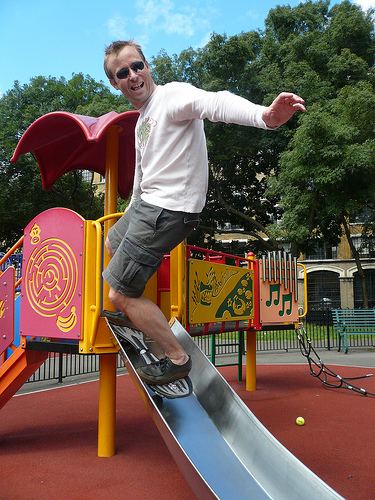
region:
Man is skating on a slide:
[82, 33, 324, 395]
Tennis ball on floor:
[292, 410, 307, 432]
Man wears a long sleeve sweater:
[81, 25, 319, 407]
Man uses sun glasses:
[85, 27, 322, 398]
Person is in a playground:
[15, 38, 367, 498]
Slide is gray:
[91, 305, 358, 498]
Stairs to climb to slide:
[1, 237, 50, 433]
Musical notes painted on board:
[259, 280, 296, 319]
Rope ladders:
[288, 323, 372, 394]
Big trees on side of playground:
[211, 2, 370, 246]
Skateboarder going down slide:
[97, 37, 305, 382]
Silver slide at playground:
[97, 302, 339, 494]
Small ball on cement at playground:
[293, 409, 302, 424]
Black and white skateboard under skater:
[110, 317, 189, 397]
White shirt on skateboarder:
[126, 87, 267, 212]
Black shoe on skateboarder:
[135, 352, 191, 385]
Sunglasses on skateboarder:
[111, 58, 146, 79]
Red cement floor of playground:
[0, 360, 372, 496]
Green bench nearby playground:
[331, 305, 372, 352]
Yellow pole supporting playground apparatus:
[92, 349, 120, 457]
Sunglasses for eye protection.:
[107, 51, 155, 84]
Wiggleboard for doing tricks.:
[109, 308, 206, 424]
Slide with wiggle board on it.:
[85, 303, 349, 498]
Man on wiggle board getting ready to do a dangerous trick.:
[72, 32, 329, 398]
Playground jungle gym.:
[2, 102, 359, 490]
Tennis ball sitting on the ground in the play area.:
[290, 407, 313, 434]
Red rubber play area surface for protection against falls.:
[25, 397, 374, 492]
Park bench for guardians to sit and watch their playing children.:
[315, 289, 373, 378]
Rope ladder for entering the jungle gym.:
[287, 293, 373, 405]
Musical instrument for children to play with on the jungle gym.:
[256, 245, 304, 329]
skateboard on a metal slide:
[78, 262, 213, 423]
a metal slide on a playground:
[93, 295, 326, 494]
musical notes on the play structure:
[251, 259, 311, 354]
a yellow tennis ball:
[283, 405, 321, 432]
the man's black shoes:
[113, 338, 218, 398]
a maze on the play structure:
[19, 219, 90, 347]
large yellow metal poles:
[80, 331, 137, 474]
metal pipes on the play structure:
[248, 239, 310, 305]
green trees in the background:
[264, 123, 357, 258]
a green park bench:
[325, 303, 374, 349]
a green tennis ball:
[295, 415, 308, 427]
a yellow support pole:
[100, 367, 116, 457]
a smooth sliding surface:
[171, 406, 271, 491]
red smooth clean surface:
[21, 434, 89, 493]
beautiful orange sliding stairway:
[0, 360, 28, 386]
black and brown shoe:
[140, 362, 192, 379]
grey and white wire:
[295, 335, 373, 394]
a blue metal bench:
[337, 311, 374, 338]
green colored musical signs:
[266, 288, 298, 321]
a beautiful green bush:
[285, 153, 363, 239]